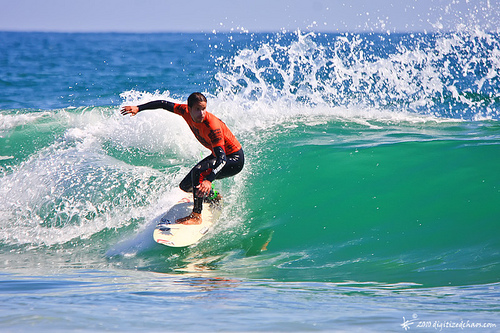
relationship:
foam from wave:
[220, 5, 499, 115] [3, 104, 499, 281]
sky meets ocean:
[1, 3, 497, 49] [0, 30, 485, 331]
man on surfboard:
[120, 92, 244, 225] [131, 175, 262, 280]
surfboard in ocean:
[134, 180, 261, 258] [30, 21, 486, 106]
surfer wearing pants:
[120, 92, 245, 225] [173, 142, 243, 222]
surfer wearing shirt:
[120, 92, 245, 225] [168, 88, 270, 157]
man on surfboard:
[119, 91, 245, 226] [153, 178, 240, 245]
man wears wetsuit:
[119, 91, 245, 226] [169, 110, 253, 190]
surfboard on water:
[152, 192, 222, 247] [2, 30, 498, 330]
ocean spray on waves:
[199, 11, 496, 127] [2, 86, 499, 289]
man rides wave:
[119, 91, 245, 226] [1, 129, 232, 289]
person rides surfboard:
[120, 92, 244, 224] [114, 172, 238, 256]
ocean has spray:
[248, 106, 499, 306] [217, 0, 494, 114]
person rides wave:
[120, 85, 247, 224] [287, 88, 430, 129]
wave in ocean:
[281, 90, 439, 297] [98, 27, 483, 139]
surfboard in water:
[152, 192, 222, 247] [225, 121, 476, 332]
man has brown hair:
[119, 91, 245, 226] [185, 89, 207, 109]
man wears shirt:
[119, 91, 245, 226] [168, 101, 243, 159]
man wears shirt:
[119, 91, 245, 226] [174, 102, 240, 161]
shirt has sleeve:
[174, 102, 240, 161] [207, 149, 229, 180]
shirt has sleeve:
[174, 102, 240, 161] [134, 99, 173, 113]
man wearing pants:
[119, 91, 245, 226] [177, 144, 245, 214]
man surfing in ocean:
[120, 92, 244, 225] [0, 30, 485, 331]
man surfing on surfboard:
[119, 91, 245, 226] [150, 191, 217, 248]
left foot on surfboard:
[172, 224, 199, 225] [154, 193, 214, 247]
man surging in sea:
[119, 91, 245, 226] [2, 1, 498, 123]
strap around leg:
[205, 186, 219, 203] [179, 178, 221, 209]